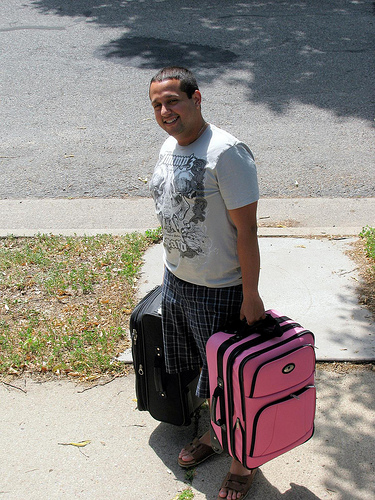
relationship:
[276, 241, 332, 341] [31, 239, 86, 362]
concrete slab between grass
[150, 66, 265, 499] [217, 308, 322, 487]
guy carrying suitcases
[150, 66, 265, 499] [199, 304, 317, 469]
guy carrying suitcase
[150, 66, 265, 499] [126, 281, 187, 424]
guy carrying suitcase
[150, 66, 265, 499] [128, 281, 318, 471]
guy carrying suitcases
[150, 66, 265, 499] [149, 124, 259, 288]
guy wearing shirt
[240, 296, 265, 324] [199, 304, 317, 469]
hand carrying suitcase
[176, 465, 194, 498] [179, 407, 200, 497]
grass growing in crack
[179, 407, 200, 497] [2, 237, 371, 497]
crack in sidewalk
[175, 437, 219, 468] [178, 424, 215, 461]
sandal on foot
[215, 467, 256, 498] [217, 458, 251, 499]
sandal on foot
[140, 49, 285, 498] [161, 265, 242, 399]
guy wearing plaid shorts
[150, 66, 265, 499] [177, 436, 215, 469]
guy wearing sandal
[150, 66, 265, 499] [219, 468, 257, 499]
guy wearing sandals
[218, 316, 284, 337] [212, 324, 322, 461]
handle on suitcase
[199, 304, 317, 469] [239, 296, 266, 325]
suitcase in hand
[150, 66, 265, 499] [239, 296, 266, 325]
guy has hand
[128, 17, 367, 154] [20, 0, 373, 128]
shadow of shadow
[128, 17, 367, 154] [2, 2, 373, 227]
shadow on asphalt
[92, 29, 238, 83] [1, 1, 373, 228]
black patch on road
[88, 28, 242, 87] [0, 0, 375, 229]
black patch on asphalt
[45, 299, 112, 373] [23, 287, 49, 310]
grass in dirt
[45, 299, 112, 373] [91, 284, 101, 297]
grass in dirt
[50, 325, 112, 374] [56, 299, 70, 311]
grass in dirt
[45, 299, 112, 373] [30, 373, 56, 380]
grass in dirt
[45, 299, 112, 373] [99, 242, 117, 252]
grass in dirt